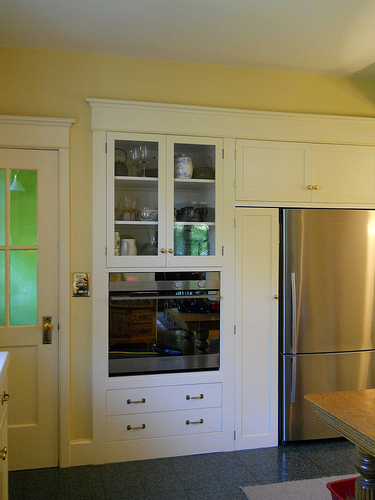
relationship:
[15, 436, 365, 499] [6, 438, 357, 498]
gray tile on floor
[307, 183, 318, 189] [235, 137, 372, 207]
handle on cabinet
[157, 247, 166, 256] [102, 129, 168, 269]
handle on cabinet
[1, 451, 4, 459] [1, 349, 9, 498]
handle on cabinet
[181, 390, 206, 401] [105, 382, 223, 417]
handle on drawer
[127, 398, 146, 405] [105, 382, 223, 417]
handle on drawer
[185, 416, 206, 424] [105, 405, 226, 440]
handle on drawer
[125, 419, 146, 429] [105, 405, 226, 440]
handle on drawer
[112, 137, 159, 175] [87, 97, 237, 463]
cabinet window on cabinet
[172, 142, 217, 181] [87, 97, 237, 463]
cabinet window on cabinet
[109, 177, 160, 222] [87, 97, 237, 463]
cabinet window on cabinet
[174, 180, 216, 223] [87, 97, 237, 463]
cabinet window on cabinet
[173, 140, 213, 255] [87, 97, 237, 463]
window on cabinet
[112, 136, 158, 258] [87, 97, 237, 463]
window on cabinet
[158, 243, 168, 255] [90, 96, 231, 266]
golden knob on cabinet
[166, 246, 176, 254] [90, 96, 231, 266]
knob on cabinet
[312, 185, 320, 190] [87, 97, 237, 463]
knob on cabinet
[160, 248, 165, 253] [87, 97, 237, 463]
golden knob on cabinet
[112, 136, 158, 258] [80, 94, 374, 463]
window on cabinets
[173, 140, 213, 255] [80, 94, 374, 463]
window on cabinets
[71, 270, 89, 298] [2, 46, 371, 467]
light switch on wall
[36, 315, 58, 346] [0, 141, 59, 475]
knob on door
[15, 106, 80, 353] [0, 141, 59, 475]
white frame on door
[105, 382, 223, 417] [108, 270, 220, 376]
drawer below oven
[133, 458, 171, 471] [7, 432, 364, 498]
tile on floor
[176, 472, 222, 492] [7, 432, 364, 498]
tile on floor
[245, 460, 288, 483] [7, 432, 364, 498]
tile on floor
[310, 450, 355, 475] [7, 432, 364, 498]
tile on floor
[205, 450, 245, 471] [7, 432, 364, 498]
tile on floor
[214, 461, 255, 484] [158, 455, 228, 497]
tile on floor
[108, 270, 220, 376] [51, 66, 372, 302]
oven in kitchen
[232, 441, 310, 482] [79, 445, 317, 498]
tile in floor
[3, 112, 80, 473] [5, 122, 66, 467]
door has windows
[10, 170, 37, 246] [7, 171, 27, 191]
window shows light fixture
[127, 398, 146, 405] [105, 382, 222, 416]
handle on drawer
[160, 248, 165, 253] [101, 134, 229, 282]
golden knob on cabinet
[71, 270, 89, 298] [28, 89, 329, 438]
light switch on wall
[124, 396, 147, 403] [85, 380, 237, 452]
handle on drawer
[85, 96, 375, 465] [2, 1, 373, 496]
cabinets in kitchen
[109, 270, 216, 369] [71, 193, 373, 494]
oven in kitchen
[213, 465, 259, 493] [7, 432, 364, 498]
tile on floor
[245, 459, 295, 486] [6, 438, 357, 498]
tile on floor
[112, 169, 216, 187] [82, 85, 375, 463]
shelf seen through cabinet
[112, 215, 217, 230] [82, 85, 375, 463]
shelf seen through cabinet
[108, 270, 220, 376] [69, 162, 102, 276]
oven on wall